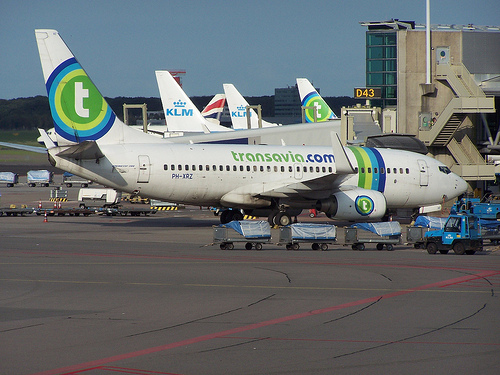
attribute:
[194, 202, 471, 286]
tarps — silver, blue, luggage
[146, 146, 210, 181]
window — Small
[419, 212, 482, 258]
vehicle — airport towing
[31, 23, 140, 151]
airplane tail — green, blue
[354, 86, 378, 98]
sign — Black, digital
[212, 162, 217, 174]
window — Small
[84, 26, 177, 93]
clouds — white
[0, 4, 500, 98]
sky — blue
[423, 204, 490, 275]
vehicle — Small, airport, blue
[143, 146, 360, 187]
window — Small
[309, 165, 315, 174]
window — Small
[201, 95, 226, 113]
stripe — blue, red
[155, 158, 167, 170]
window — Small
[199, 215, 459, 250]
baggage carts — lined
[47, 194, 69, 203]
caution paint — black, yellow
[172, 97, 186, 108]
logo — crown, blue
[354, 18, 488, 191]
building — airport, six floor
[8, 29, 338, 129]
fins — tail 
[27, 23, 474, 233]
plane — passenger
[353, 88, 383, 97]
lights — orange 